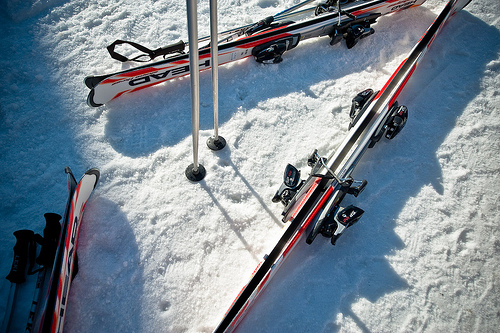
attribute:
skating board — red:
[207, 0, 475, 332]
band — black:
[110, 34, 154, 64]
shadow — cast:
[105, 44, 364, 150]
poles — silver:
[166, 11, 246, 184]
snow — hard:
[116, 183, 236, 265]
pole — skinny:
[182, 6, 255, 183]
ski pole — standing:
[184, 2, 203, 180]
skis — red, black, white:
[88, 0, 406, 114]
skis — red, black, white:
[38, 162, 101, 328]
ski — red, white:
[2, 159, 105, 321]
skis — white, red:
[89, 0, 444, 330]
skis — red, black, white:
[215, 2, 482, 331]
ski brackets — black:
[268, 145, 372, 238]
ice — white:
[140, 205, 188, 245]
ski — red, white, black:
[217, 0, 454, 331]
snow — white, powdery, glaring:
[1, 0, 497, 331]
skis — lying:
[89, 39, 323, 73]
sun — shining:
[137, 171, 207, 240]